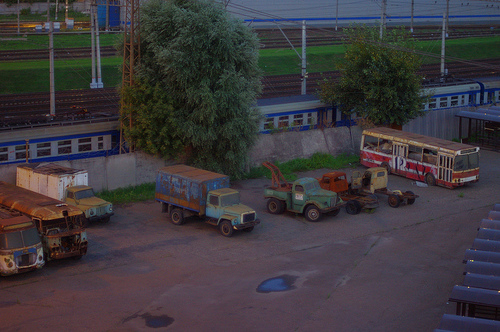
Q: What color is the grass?
A: Green.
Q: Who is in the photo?
A: No one.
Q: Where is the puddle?
A: On the ground.